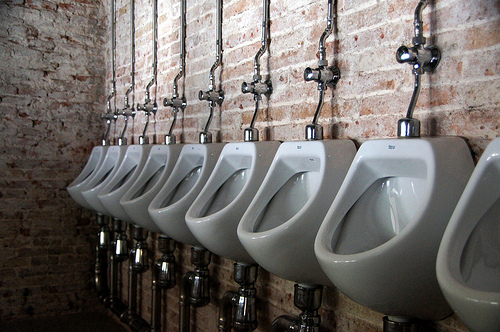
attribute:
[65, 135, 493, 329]
urinals — white, attached, ceramic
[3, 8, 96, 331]
wall — brick, red, faded, white, orange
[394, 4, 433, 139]
pipe — silver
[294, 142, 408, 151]
printing — black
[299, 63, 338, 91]
handle — silver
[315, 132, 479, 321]
bowl — white